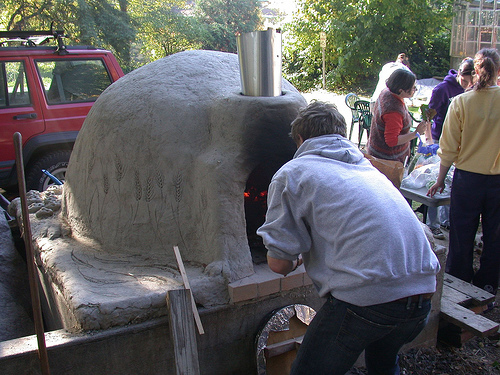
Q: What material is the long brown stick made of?
A: Wood.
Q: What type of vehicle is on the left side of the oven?
A: A jeep.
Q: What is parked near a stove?
A: A jeep.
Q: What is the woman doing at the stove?
A: Cooking.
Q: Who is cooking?
A: A woman.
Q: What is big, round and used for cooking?
A: An oven.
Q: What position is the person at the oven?
A: Bending forward.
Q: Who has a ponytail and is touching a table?
A: A woman.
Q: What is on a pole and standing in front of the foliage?
A: A sign.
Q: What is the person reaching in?
A: Oven.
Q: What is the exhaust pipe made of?
A: Metal.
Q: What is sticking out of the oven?
A: Exhaust pipe.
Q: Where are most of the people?
A: Around the table.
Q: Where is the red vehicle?
A: Behind the oven.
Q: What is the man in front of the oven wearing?
A: Hoodie.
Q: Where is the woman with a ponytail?
A: In front of the table.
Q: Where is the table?
A: To the right of the oven.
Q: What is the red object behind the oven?
A: Car.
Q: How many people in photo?
A: Five.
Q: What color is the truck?
A: Red.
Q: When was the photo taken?
A: Daytime.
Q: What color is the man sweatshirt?
A: Grey.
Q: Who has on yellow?
A: Woman on the right.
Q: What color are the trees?
A: Green.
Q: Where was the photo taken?
A: At an outdoor oven.